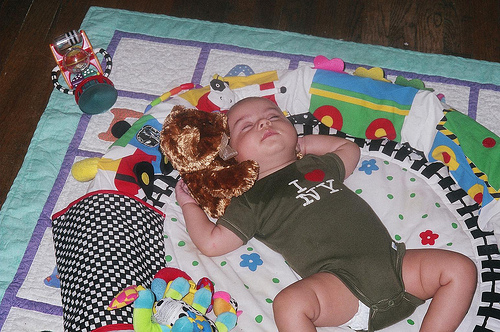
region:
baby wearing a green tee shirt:
[208, 152, 408, 267]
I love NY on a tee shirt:
[280, 168, 363, 232]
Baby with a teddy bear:
[162, 101, 242, 203]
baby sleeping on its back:
[196, 68, 448, 318]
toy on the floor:
[115, 273, 199, 330]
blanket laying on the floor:
[58, 10, 201, 101]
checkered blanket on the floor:
[34, 187, 159, 312]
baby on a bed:
[147, 73, 373, 187]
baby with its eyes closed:
[236, 113, 293, 139]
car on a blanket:
[102, 151, 159, 183]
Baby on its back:
[170, 89, 484, 329]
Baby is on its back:
[158, 92, 480, 330]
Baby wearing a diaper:
[341, 252, 380, 329]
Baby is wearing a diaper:
[336, 270, 381, 330]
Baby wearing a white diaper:
[337, 279, 389, 329]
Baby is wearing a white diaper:
[339, 287, 381, 329]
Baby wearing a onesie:
[210, 147, 429, 328]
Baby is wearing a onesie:
[209, 146, 427, 330]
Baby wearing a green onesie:
[218, 149, 425, 330]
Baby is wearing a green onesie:
[212, 150, 431, 329]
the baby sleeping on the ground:
[175, 95, 477, 329]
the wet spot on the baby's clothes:
[237, 160, 305, 205]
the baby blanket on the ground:
[0, 5, 497, 330]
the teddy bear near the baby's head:
[160, 103, 259, 218]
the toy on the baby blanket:
[50, 28, 117, 112]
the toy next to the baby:
[107, 265, 238, 330]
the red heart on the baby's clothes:
[302, 168, 324, 183]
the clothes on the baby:
[216, 151, 425, 330]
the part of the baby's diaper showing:
[339, 296, 369, 330]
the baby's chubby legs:
[272, 246, 477, 330]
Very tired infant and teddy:
[173, 94, 475, 329]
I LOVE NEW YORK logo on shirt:
[287, 165, 341, 213]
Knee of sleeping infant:
[435, 248, 473, 307]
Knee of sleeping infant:
[271, 288, 308, 330]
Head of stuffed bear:
[159, 102, 230, 167]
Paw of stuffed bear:
[232, 161, 257, 188]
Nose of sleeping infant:
[255, 118, 273, 128]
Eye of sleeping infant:
[237, 121, 256, 131]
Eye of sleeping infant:
[265, 113, 281, 121]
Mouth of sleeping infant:
[256, 128, 283, 142]